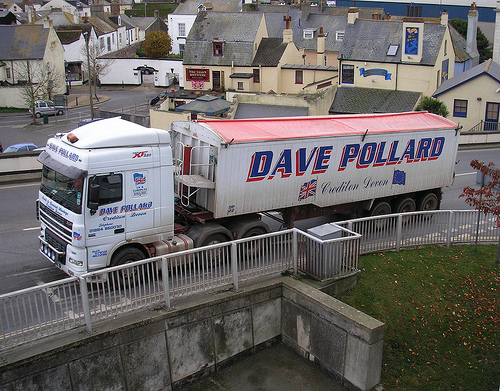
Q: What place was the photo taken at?
A: It was taken at the road.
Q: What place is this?
A: It is a road.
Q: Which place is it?
A: It is a road.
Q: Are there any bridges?
A: Yes, there is a bridge.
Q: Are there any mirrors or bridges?
A: Yes, there is a bridge.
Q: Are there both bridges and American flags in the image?
A: No, there is a bridge but no American flags.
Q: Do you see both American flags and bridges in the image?
A: No, there is a bridge but no American flags.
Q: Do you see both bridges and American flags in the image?
A: No, there is a bridge but no American flags.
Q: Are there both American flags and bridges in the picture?
A: No, there is a bridge but no American flags.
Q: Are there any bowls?
A: No, there are no bowls.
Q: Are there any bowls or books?
A: No, there are no bowls or books.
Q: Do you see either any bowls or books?
A: No, there are no bowls or books.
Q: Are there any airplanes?
A: No, there are no airplanes.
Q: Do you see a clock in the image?
A: No, there are no clocks.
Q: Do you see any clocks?
A: No, there are no clocks.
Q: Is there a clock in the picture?
A: No, there are no clocks.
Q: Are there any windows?
A: Yes, there is a window.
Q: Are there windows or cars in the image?
A: Yes, there is a window.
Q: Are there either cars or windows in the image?
A: Yes, there is a window.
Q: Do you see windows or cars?
A: Yes, there is a window.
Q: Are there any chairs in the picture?
A: No, there are no chairs.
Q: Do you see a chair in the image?
A: No, there are no chairs.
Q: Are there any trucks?
A: Yes, there is a truck.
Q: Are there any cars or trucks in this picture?
A: Yes, there is a truck.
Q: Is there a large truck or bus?
A: Yes, there is a large truck.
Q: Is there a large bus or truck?
A: Yes, there is a large truck.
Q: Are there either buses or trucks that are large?
A: Yes, the truck is large.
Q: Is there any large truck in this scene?
A: Yes, there is a large truck.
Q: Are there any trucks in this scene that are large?
A: Yes, there is a truck that is large.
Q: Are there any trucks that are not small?
A: Yes, there is a large truck.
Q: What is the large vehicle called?
A: The vehicle is a truck.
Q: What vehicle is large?
A: The vehicle is a truck.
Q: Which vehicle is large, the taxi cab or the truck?
A: The truck is large.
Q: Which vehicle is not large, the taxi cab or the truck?
A: The taxi cab is not large.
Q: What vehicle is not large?
A: The vehicle is a taxi.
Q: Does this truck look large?
A: Yes, the truck is large.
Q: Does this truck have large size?
A: Yes, the truck is large.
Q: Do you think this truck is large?
A: Yes, the truck is large.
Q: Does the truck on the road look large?
A: Yes, the truck is large.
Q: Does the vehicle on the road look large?
A: Yes, the truck is large.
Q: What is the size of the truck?
A: The truck is large.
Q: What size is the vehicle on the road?
A: The truck is large.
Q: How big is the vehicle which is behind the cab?
A: The truck is large.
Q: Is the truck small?
A: No, the truck is large.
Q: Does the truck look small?
A: No, the truck is large.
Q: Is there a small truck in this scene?
A: No, there is a truck but it is large.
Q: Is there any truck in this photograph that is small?
A: No, there is a truck but it is large.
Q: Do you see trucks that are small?
A: No, there is a truck but it is large.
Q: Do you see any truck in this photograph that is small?
A: No, there is a truck but it is large.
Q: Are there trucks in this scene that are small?
A: No, there is a truck but it is large.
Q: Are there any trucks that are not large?
A: No, there is a truck but it is large.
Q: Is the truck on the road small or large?
A: The truck is large.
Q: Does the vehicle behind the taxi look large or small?
A: The truck is large.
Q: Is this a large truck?
A: Yes, this is a large truck.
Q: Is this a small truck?
A: No, this is a large truck.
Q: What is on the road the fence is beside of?
A: The truck is on the road.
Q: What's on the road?
A: The truck is on the road.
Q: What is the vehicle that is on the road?
A: The vehicle is a truck.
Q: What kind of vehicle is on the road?
A: The vehicle is a truck.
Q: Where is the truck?
A: The truck is on the road.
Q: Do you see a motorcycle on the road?
A: No, there is a truck on the road.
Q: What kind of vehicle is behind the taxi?
A: The vehicle is a truck.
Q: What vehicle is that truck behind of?
A: The truck is behind the taxi cab.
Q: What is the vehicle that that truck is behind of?
A: The vehicle is a taxi.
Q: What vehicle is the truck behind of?
A: The truck is behind the taxi cab.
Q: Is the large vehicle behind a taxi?
A: Yes, the truck is behind a taxi.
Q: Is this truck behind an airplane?
A: No, the truck is behind a taxi.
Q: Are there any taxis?
A: Yes, there is a taxi.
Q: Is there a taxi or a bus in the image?
A: Yes, there is a taxi.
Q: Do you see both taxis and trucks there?
A: Yes, there are both a taxi and a truck.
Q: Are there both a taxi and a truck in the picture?
A: Yes, there are both a taxi and a truck.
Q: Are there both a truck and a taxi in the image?
A: Yes, there are both a taxi and a truck.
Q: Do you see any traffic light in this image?
A: No, there are no traffic lights.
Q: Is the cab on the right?
A: No, the cab is on the left of the image.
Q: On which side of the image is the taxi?
A: The taxi is on the left of the image.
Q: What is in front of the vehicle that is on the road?
A: The taxi cab is in front of the truck.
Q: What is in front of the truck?
A: The taxi cab is in front of the truck.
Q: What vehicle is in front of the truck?
A: The vehicle is a taxi.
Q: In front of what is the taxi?
A: The taxi is in front of the truck.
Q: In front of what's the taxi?
A: The taxi is in front of the truck.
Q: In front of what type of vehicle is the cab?
A: The cab is in front of the truck.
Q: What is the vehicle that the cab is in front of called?
A: The vehicle is a truck.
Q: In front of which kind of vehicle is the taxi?
A: The cab is in front of the truck.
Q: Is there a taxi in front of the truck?
A: Yes, there is a taxi in front of the truck.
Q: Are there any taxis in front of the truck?
A: Yes, there is a taxi in front of the truck.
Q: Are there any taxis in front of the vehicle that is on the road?
A: Yes, there is a taxi in front of the truck.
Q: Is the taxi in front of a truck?
A: Yes, the taxi is in front of a truck.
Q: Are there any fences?
A: Yes, there is a fence.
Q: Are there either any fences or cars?
A: Yes, there is a fence.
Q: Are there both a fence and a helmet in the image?
A: No, there is a fence but no helmets.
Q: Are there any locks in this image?
A: No, there are no locks.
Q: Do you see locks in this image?
A: No, there are no locks.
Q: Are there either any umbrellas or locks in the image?
A: No, there are no locks or umbrellas.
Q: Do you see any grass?
A: Yes, there is grass.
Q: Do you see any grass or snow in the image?
A: Yes, there is grass.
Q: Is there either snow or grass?
A: Yes, there is grass.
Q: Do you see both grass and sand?
A: No, there is grass but no sand.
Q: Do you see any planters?
A: No, there are no planters.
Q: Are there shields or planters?
A: No, there are no planters or shields.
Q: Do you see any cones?
A: No, there are no cones.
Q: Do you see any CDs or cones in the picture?
A: No, there are no cones or cds.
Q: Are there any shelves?
A: No, there are no shelves.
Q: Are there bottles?
A: No, there are no bottles.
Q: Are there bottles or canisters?
A: No, there are no bottles or canisters.